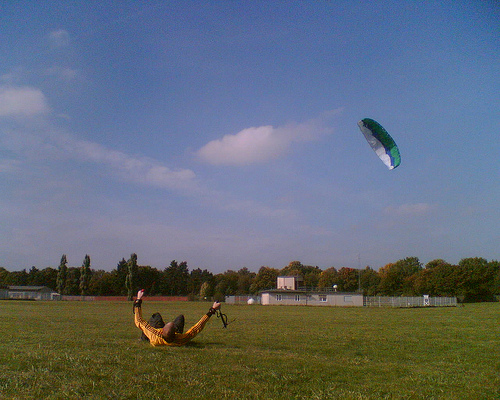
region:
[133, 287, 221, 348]
Man on his back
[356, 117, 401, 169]
White blue and green kite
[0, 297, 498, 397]
Grassy open field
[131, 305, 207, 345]
Yellow and black shirt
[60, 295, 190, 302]
Orange mesh fencing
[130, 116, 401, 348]
Man flying his kite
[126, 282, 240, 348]
A man is on the ground.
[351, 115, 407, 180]
The kite is in the air.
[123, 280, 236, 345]
The man is wearing yellow.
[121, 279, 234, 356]
A man is flying a kite.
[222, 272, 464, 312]
A building is in the background.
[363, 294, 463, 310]
A fence is by a building.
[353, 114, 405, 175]
The kite is green and blue.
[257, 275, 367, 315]
The building is made of brick.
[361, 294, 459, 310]
The fence is made of metal.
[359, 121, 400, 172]
white and green kite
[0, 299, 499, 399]
grass field man is laying on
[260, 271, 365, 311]
white building in the distance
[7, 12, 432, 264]
white wispy clouds in the sky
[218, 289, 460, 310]
white fence around white building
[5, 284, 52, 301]
building on the left side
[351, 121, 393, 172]
white section of the kite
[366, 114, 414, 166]
green section of the kite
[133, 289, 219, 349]
A man on the ground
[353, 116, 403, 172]
A kite in the air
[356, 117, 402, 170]
The kite is green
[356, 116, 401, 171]
The Kite is white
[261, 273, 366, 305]
A building in the background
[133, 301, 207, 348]
The man's shirt is yellow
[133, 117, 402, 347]
A man flying a kite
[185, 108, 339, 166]
A white cloud in the sky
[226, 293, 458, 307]
A fence in the background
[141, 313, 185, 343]
A man wearing pants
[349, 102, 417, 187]
Kite is in the air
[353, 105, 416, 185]
Large kite in the air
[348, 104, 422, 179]
Green, blue and white colored kite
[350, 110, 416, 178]
Green, blue and white colored kite is in the air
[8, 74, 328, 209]
White clouds in the sky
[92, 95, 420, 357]
Man is flying a kite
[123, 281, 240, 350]
The man is laying down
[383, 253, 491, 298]
Green trees in the background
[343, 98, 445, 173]
The man is flying a kite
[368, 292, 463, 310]
The white barrier fence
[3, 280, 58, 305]
The house to the far left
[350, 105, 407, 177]
A green and white kite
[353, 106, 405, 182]
green and white kite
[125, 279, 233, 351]
laying man holding kite string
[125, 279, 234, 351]
man laying on back on ground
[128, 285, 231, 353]
man in yellow shirt laying down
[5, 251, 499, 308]
row of trees in background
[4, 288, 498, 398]
large green grassy field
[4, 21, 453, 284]
fluffy white clouds in sky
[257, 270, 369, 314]
cream colored distant building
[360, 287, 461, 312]
white fence near building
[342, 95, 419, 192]
The kite is green and white.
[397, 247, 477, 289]
The trees are green.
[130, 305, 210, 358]
The man is wearing yellow.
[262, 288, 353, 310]
A building is in the distance.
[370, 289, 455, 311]
A fence is next to the building.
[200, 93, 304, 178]
There are clouds in the sky.